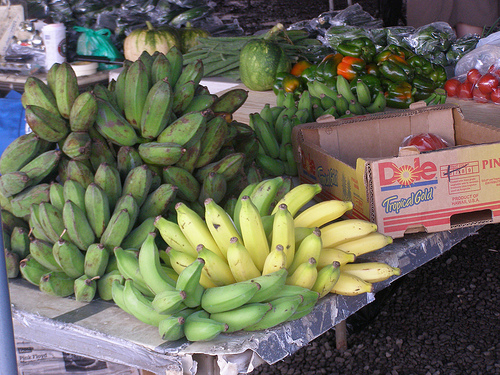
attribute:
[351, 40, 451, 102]
peppers — green 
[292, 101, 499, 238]
box — brown 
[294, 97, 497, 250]
box — large, square, cardboard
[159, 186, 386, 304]
bananas — yellow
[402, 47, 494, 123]
tomatoes — red 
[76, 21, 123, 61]
ribbon — aqua blue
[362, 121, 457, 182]
pepper — red 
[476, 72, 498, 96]
tomato — red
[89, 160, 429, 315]
bananas — yellow 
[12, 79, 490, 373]
table — broken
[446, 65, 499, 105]
tomatoes — red 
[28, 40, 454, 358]
bananas — green 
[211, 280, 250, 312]
banana — green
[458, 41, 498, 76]
bag — paper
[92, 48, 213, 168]
bananas — green 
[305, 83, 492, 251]
box — carton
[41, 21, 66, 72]
mug — coffee, polystyrene, take-out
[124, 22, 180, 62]
pumpkin squash — white, green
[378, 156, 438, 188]
dole — red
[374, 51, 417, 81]
bell pepper — green, spotted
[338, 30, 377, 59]
bell pepper — spotted, green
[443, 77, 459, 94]
tomato — small, ripe, red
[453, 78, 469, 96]
tomato — small, ripe, red